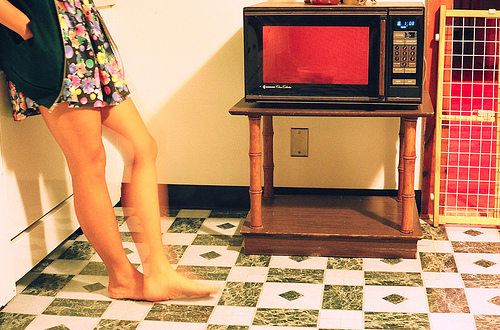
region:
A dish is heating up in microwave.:
[229, 4, 425, 109]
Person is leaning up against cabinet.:
[0, 0, 224, 304]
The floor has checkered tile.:
[1, 206, 498, 328]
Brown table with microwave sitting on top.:
[234, 0, 429, 261]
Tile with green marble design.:
[322, 283, 363, 310]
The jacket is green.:
[0, 0, 63, 105]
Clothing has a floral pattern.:
[8, 0, 136, 120]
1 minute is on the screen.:
[392, 12, 419, 31]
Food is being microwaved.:
[237, 5, 424, 107]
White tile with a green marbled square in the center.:
[362, 285, 427, 313]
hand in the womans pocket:
[2, 5, 57, 45]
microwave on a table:
[240, 5, 442, 113]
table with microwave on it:
[220, 88, 459, 268]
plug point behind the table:
[273, 116, 320, 159]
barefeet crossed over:
[103, 255, 230, 302]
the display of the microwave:
[390, 15, 429, 32]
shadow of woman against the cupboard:
[2, 80, 96, 286]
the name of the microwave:
[256, 77, 299, 94]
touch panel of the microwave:
[393, 28, 420, 90]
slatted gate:
[430, 5, 495, 249]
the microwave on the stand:
[241, 3, 426, 108]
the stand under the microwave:
[227, 87, 434, 259]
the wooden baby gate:
[432, 4, 498, 231]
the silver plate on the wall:
[289, 127, 309, 157]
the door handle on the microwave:
[376, 16, 386, 96]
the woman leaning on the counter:
[0, 0, 220, 302]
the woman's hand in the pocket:
[1, 0, 68, 113]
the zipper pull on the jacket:
[47, 104, 55, 114]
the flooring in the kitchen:
[0, 206, 497, 329]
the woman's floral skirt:
[7, 0, 131, 122]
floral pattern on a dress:
[49, 20, 114, 106]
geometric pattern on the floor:
[244, 248, 343, 328]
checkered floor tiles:
[248, 261, 370, 322]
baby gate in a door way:
[448, 24, 499, 184]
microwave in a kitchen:
[227, 1, 432, 111]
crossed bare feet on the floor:
[87, 233, 225, 318]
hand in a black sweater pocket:
[1, 11, 46, 73]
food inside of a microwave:
[287, 46, 342, 87]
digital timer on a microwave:
[394, 17, 422, 29]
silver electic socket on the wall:
[290, 127, 310, 159]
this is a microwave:
[245, 7, 423, 103]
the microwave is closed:
[245, 3, 425, 100]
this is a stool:
[245, 118, 417, 241]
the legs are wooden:
[385, 105, 434, 250]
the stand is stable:
[289, 199, 384, 252]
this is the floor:
[301, 266, 413, 328]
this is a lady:
[40, 15, 187, 288]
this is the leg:
[78, 174, 111, 251]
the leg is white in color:
[62, 114, 97, 143]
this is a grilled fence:
[442, 15, 488, 223]